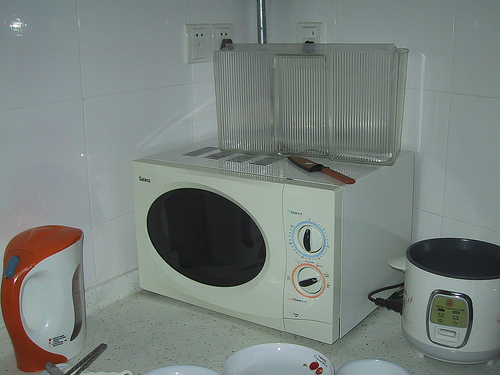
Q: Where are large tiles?
A: On the wall.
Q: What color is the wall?
A: White.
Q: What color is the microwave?
A: White.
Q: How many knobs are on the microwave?
A: Two.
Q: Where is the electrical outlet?
A: Corner above the microwave.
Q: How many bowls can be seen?
A: Three.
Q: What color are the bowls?
A: White.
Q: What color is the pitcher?
A: Orange and white.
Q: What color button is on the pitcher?
A: Blue.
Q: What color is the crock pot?
A: White.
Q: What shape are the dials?
A: Round.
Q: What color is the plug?
A: Black.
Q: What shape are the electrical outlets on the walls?
A: Square.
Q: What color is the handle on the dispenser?
A: Red.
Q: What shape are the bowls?
A: Round.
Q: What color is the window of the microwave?
A: Black.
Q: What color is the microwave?
A: Off-white.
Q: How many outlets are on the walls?
A: Three.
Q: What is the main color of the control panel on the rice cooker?
A: Green.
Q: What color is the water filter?
A: Red and white.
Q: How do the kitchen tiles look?
A: Glossy and white.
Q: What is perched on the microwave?
A: Clear trays.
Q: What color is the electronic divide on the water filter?
A: Orange and white.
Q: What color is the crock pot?
A: White, black, and green.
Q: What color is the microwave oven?
A: Black and white.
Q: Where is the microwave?
A: On the white table.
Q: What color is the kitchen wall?
A: White.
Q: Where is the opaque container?
A: On the white microwave.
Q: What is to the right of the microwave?
A: Crockpot.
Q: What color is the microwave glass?
A: Black.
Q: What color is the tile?
A: White.